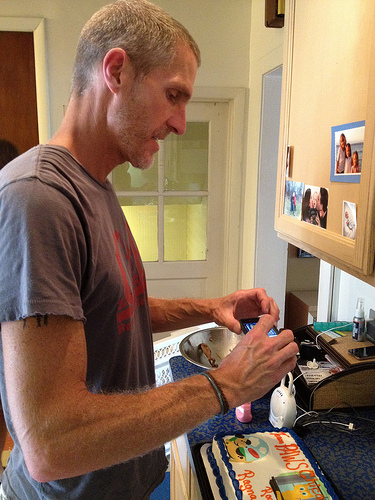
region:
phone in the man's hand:
[243, 314, 276, 341]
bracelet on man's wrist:
[199, 362, 236, 424]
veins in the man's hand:
[217, 341, 272, 392]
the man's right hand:
[215, 316, 303, 418]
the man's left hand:
[208, 284, 278, 331]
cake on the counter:
[182, 429, 327, 498]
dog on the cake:
[222, 436, 252, 469]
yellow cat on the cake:
[282, 482, 312, 499]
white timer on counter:
[262, 370, 300, 425]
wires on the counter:
[296, 407, 366, 435]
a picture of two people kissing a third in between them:
[300, 183, 328, 230]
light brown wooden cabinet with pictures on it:
[275, 4, 371, 283]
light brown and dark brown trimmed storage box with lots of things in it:
[279, 320, 370, 408]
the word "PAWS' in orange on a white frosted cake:
[274, 443, 312, 469]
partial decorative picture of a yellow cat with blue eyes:
[274, 484, 314, 498]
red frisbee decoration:
[246, 446, 260, 459]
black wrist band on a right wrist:
[198, 369, 231, 420]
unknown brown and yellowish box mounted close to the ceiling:
[262, 1, 289, 30]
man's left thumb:
[211, 309, 241, 334]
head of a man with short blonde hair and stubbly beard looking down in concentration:
[51, 2, 202, 186]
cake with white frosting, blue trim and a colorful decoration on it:
[191, 428, 342, 497]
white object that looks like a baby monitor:
[268, 371, 303, 430]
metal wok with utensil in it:
[178, 325, 249, 371]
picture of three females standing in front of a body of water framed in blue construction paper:
[329, 119, 361, 184]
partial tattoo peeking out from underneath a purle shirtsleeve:
[16, 307, 51, 330]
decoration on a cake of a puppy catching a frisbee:
[221, 433, 261, 466]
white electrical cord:
[295, 401, 356, 429]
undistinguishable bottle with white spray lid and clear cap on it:
[352, 297, 366, 340]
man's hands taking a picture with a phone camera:
[213, 285, 300, 411]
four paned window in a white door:
[107, 119, 210, 262]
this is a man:
[30, 13, 293, 495]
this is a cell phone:
[233, 297, 300, 364]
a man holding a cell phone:
[21, 5, 293, 495]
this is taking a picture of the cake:
[168, 262, 338, 498]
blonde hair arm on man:
[58, 378, 228, 478]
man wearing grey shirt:
[12, 145, 178, 489]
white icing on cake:
[212, 431, 313, 495]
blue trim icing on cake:
[212, 428, 334, 498]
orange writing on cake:
[271, 434, 304, 498]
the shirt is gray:
[0, 143, 169, 498]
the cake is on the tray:
[190, 427, 342, 498]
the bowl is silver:
[179, 326, 245, 373]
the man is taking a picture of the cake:
[1, 0, 342, 498]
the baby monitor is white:
[268, 370, 296, 430]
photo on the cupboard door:
[329, 120, 364, 183]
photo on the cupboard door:
[342, 201, 356, 240]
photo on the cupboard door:
[302, 184, 329, 226]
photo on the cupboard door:
[283, 181, 304, 219]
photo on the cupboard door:
[285, 145, 290, 176]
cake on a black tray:
[192, 425, 339, 498]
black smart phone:
[238, 317, 277, 336]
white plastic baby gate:
[152, 321, 216, 453]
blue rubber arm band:
[200, 371, 225, 418]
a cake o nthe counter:
[217, 435, 279, 494]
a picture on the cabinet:
[317, 118, 365, 182]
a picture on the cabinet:
[293, 186, 344, 221]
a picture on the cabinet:
[328, 204, 371, 240]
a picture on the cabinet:
[275, 173, 315, 226]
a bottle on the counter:
[335, 296, 374, 345]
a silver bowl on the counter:
[146, 309, 264, 403]